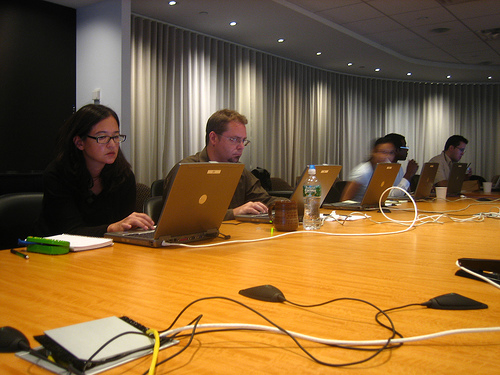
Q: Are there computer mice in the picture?
A: Yes, there is a computer mouse.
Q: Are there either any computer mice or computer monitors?
A: Yes, there is a computer mouse.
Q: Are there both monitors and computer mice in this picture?
A: No, there is a computer mouse but no monitors.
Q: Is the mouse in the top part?
A: No, the mouse is in the bottom of the image.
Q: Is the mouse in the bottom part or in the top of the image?
A: The mouse is in the bottom of the image.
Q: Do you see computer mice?
A: Yes, there is a computer mouse.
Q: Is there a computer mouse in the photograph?
A: Yes, there is a computer mouse.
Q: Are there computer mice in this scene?
A: Yes, there is a computer mouse.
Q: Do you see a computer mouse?
A: Yes, there is a computer mouse.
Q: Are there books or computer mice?
A: Yes, there is a computer mouse.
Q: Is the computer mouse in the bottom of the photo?
A: Yes, the computer mouse is in the bottom of the image.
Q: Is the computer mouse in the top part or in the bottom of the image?
A: The computer mouse is in the bottom of the image.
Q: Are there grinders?
A: No, there are no grinders.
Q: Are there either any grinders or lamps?
A: No, there are no grinders or lamps.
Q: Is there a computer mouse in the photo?
A: Yes, there is a computer mouse.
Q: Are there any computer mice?
A: Yes, there is a computer mouse.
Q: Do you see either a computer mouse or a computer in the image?
A: Yes, there is a computer mouse.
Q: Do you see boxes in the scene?
A: No, there are no boxes.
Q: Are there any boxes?
A: No, there are no boxes.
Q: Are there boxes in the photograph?
A: No, there are no boxes.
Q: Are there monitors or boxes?
A: No, there are no boxes or monitors.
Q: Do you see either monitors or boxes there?
A: No, there are no boxes or monitors.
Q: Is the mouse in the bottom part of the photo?
A: Yes, the mouse is in the bottom of the image.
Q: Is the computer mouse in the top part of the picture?
A: No, the computer mouse is in the bottom of the image.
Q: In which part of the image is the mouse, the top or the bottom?
A: The mouse is in the bottom of the image.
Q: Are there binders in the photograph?
A: No, there are no binders.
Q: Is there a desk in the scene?
A: Yes, there is a desk.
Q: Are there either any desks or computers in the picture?
A: Yes, there is a desk.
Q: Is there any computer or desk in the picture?
A: Yes, there is a desk.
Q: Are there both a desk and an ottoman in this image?
A: No, there is a desk but no ottomen.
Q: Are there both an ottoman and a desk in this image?
A: No, there is a desk but no ottomen.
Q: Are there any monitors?
A: No, there are no monitors.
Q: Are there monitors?
A: No, there are no monitors.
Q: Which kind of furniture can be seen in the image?
A: The furniture is a desk.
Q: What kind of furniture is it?
A: The piece of furniture is a desk.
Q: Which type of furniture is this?
A: That is a desk.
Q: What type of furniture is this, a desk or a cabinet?
A: That is a desk.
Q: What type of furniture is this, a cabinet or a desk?
A: That is a desk.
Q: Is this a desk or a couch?
A: This is a desk.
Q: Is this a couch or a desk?
A: This is a desk.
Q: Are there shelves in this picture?
A: No, there are no shelves.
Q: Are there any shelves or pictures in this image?
A: No, there are no shelves or pictures.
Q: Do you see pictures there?
A: No, there are no pictures.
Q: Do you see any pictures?
A: No, there are no pictures.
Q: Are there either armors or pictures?
A: No, there are no pictures or armors.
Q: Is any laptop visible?
A: Yes, there is a laptop.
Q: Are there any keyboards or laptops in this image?
A: Yes, there is a laptop.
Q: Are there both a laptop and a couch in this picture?
A: No, there is a laptop but no couches.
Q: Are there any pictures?
A: No, there are no pictures.